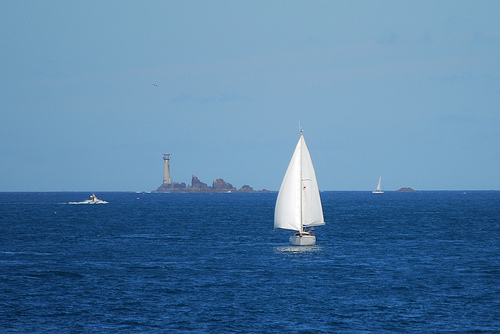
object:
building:
[212, 177, 237, 193]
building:
[238, 184, 255, 192]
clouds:
[190, 15, 386, 86]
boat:
[271, 124, 326, 246]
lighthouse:
[161, 151, 171, 182]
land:
[157, 177, 266, 194]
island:
[151, 186, 269, 193]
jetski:
[82, 191, 99, 204]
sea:
[2, 185, 499, 331]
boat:
[371, 173, 385, 194]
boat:
[89, 193, 99, 203]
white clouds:
[99, 53, 129, 104]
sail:
[272, 126, 326, 230]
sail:
[377, 176, 382, 190]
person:
[90, 193, 95, 200]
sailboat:
[370, 175, 387, 195]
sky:
[0, 0, 500, 194]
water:
[0, 187, 500, 334]